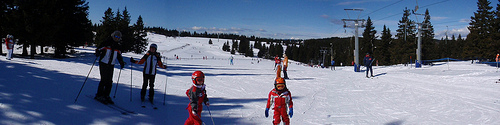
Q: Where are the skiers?
A: On slopes.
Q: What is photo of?
A: Skiers at a resort.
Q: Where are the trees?
A: Along the ski slope.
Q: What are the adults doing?
A: Skiing.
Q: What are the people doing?
A: Skiing.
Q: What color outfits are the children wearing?
A: Red.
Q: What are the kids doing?
A: Skiing on the slopes.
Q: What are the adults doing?
A: Skiing on the slopes.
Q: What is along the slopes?
A: Trees.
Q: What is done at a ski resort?
A: Skiing.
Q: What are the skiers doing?
A: Skiing.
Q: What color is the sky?
A: Blue.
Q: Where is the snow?
A: On the ground.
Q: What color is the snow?
A: White.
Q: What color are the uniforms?
A: Red.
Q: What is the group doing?
A: Skiing.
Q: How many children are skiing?
A: Two.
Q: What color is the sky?
A: Blue.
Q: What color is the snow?
A: White.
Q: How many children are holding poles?
A: One.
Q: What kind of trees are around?
A: Pine trees.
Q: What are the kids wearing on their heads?
A: Helmets.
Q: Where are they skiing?
A: A ski resort.